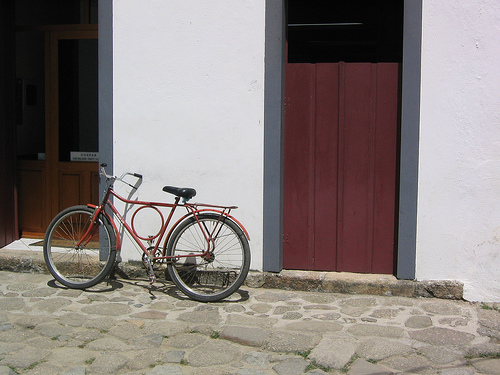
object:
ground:
[1, 249, 500, 372]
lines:
[280, 37, 402, 284]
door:
[259, 1, 431, 284]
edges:
[398, 0, 418, 282]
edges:
[258, 1, 288, 277]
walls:
[113, 1, 267, 276]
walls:
[415, 2, 499, 283]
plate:
[67, 148, 102, 170]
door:
[7, 0, 110, 250]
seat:
[161, 184, 199, 202]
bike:
[40, 156, 257, 305]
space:
[41, 1, 101, 29]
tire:
[162, 209, 255, 305]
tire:
[40, 201, 121, 290]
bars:
[99, 161, 144, 185]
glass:
[50, 35, 106, 162]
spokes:
[177, 219, 244, 297]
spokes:
[50, 211, 109, 281]